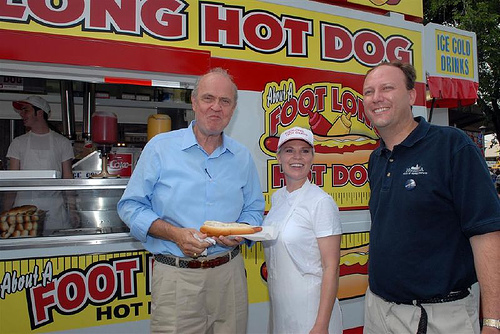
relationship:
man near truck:
[352, 51, 499, 332] [0, 3, 480, 331]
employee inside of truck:
[4, 86, 93, 229] [0, 14, 176, 308]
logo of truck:
[254, 76, 394, 234] [0, 3, 480, 331]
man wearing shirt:
[352, 51, 499, 332] [362, 113, 497, 303]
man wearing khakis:
[352, 51, 499, 332] [122, 226, 276, 329]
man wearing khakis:
[117, 65, 271, 333] [149, 253, 259, 332]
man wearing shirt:
[117, 65, 271, 333] [130, 120, 277, 270]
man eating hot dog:
[117, 65, 271, 333] [198, 216, 259, 237]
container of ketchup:
[83, 97, 126, 146] [75, 102, 130, 153]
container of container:
[146, 111, 172, 140] [146, 113, 172, 140]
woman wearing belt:
[261, 126, 346, 332] [439, 287, 467, 314]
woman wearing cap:
[261, 126, 346, 332] [276, 127, 314, 145]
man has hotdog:
[117, 65, 271, 333] [190, 203, 263, 254]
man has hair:
[151, 55, 258, 175] [190, 68, 240, 98]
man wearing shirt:
[117, 65, 271, 333] [118, 110, 265, 260]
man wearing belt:
[117, 65, 271, 333] [156, 245, 241, 267]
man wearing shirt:
[117, 65, 271, 333] [134, 119, 301, 266]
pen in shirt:
[176, 153, 230, 191] [134, 119, 301, 266]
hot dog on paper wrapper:
[197, 220, 257, 237] [239, 225, 282, 241]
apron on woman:
[258, 186, 359, 331] [246, 125, 360, 332]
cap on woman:
[273, 121, 322, 153] [268, 129, 358, 332]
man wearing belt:
[117, 65, 271, 333] [151, 253, 246, 270]